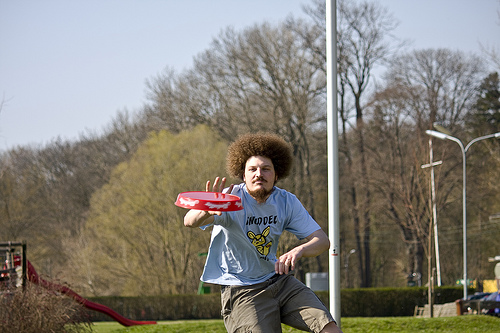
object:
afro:
[223, 129, 292, 181]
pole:
[324, 0, 344, 332]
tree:
[0, 0, 499, 292]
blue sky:
[0, 0, 499, 153]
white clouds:
[0, 0, 499, 153]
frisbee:
[172, 191, 244, 213]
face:
[243, 156, 277, 196]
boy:
[182, 129, 349, 333]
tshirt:
[198, 182, 322, 288]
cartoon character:
[243, 225, 274, 257]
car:
[466, 292, 500, 318]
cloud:
[0, 0, 499, 150]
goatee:
[245, 186, 276, 203]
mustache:
[251, 176, 268, 184]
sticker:
[329, 247, 339, 257]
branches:
[79, 159, 102, 190]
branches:
[405, 66, 441, 103]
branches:
[345, 73, 362, 96]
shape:
[204, 200, 233, 210]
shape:
[233, 199, 247, 208]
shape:
[176, 197, 200, 208]